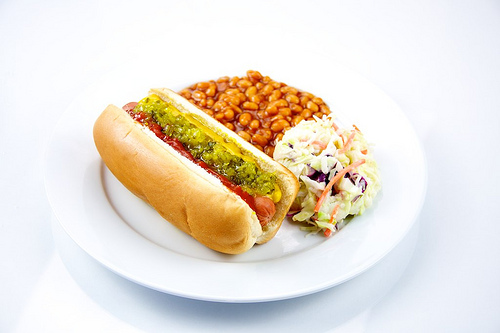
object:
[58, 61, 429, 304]
plate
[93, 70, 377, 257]
food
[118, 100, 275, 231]
hotdog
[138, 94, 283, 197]
condiments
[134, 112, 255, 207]
ketchup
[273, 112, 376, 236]
coleslaw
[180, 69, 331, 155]
beans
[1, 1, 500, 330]
background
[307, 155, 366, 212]
carrot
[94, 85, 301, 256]
bun